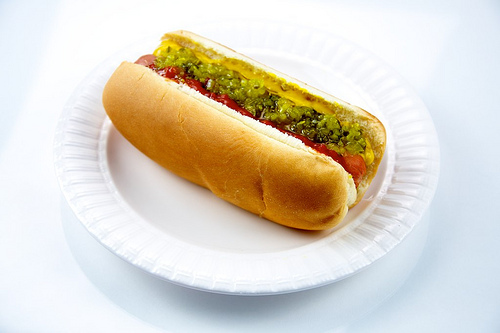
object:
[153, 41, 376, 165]
condiments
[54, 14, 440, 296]
paper plate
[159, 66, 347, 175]
ketchup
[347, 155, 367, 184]
hotdog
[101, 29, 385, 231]
hot dog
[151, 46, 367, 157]
mustard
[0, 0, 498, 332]
table